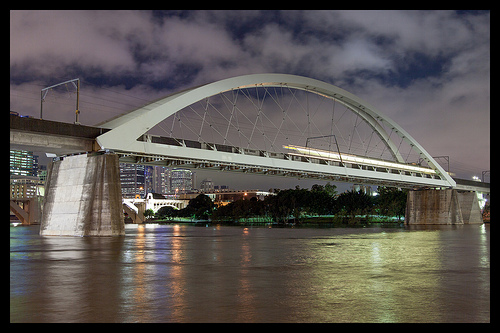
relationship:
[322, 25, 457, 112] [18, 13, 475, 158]
clouds in sky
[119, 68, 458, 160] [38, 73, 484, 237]
arch over bridge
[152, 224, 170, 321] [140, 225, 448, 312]
purple light reflecting off water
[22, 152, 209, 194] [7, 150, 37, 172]
buildings lit lit with windows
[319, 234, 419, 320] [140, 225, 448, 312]
light on water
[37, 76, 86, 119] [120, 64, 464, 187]
structure over bridge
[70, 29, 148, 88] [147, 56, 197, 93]
clouds in sky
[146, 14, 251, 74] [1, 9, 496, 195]
cloud in sky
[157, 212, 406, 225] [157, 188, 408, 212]
green lighting near trees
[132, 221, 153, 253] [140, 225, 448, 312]
lighting on water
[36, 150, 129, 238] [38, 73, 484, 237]
support on bridge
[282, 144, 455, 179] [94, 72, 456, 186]
train moves over arch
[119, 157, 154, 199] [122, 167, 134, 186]
building have windows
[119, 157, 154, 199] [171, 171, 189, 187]
building have windows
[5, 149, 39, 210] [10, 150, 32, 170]
building have windows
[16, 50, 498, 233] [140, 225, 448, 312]
bridge above water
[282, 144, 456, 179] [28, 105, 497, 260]
train on bridge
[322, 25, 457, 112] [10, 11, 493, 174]
clouds in sky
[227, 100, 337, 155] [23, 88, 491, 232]
wires on bridge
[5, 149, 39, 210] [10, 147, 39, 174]
building on building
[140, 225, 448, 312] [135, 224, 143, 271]
water has reflecting lights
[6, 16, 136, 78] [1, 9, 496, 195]
clouds in sky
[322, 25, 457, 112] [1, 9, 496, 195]
clouds in sky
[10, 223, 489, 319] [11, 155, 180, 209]
grayish water reflecting city lights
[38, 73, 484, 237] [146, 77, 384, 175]
bridge has arch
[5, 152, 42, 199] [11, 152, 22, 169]
building has buildings lit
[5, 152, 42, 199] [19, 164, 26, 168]
building has window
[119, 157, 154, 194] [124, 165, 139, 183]
building has windows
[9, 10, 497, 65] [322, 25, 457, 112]
sky has clouds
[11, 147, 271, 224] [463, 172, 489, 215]
city has lights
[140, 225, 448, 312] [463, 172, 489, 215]
water reflecting lights